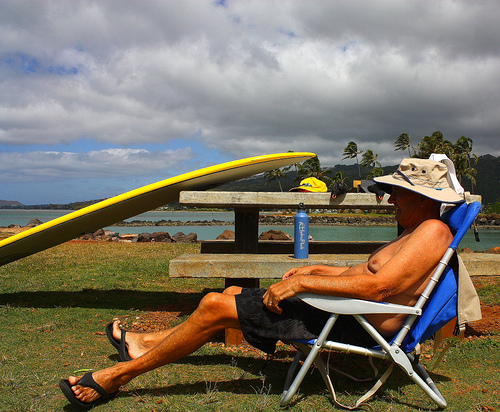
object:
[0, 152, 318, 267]
surfboard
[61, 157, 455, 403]
man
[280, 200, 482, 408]
lawn chair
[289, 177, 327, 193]
baseball cap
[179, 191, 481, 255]
picnic table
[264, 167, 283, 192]
palm tree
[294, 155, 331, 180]
palm tree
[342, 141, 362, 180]
palm tree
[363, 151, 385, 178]
palm tree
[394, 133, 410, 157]
palm tree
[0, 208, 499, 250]
river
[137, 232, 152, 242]
rock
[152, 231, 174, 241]
rock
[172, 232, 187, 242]
rock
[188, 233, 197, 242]
rock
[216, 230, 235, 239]
rock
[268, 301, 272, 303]
wedding ring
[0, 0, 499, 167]
clouds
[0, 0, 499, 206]
sky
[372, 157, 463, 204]
hat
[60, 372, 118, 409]
flip flop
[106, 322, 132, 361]
flip flop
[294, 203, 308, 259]
water bottle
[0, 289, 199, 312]
shadow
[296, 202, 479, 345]
lining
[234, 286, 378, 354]
shorts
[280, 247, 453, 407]
metal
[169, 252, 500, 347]
bench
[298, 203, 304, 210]
cap